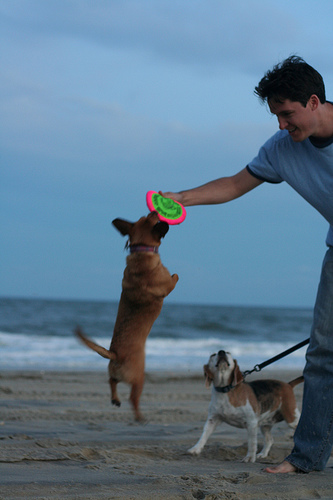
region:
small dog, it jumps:
[68, 202, 187, 427]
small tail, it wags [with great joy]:
[66, 317, 119, 366]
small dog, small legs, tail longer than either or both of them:
[68, 322, 154, 429]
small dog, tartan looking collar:
[118, 239, 159, 258]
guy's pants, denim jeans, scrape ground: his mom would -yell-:
[281, 242, 332, 474]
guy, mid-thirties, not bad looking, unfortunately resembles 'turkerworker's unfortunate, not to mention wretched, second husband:
[252, 45, 331, 157]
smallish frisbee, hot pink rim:
[143, 187, 190, 227]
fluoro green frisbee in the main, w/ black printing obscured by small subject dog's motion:
[149, 192, 182, 218]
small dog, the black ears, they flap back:
[108, 216, 176, 246]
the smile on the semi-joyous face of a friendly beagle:
[213, 345, 231, 371]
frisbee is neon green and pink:
[120, 180, 201, 245]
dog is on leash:
[200, 311, 309, 420]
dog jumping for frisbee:
[113, 182, 199, 417]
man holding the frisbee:
[145, 143, 248, 235]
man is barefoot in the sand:
[251, 443, 331, 493]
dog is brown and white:
[200, 332, 303, 487]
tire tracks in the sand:
[18, 367, 100, 449]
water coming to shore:
[31, 325, 75, 385]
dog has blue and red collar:
[109, 237, 177, 261]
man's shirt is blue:
[243, 131, 331, 185]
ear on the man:
[307, 96, 321, 110]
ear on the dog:
[198, 362, 213, 386]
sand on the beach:
[51, 427, 126, 472]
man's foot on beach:
[265, 461, 294, 477]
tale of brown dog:
[69, 328, 112, 361]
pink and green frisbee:
[148, 189, 184, 222]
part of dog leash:
[241, 349, 301, 373]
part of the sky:
[23, 97, 157, 149]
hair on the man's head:
[292, 68, 316, 93]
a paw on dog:
[238, 450, 257, 464]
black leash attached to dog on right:
[253, 342, 320, 372]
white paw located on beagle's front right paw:
[190, 431, 218, 460]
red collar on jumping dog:
[113, 228, 171, 276]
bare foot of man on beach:
[257, 456, 309, 479]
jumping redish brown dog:
[68, 208, 177, 436]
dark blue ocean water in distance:
[11, 289, 97, 331]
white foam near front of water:
[23, 329, 61, 368]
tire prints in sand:
[26, 385, 106, 455]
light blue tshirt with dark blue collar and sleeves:
[237, 127, 331, 225]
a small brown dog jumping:
[80, 205, 177, 415]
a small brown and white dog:
[185, 342, 303, 461]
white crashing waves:
[1, 329, 326, 368]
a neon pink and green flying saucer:
[142, 186, 189, 227]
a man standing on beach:
[158, 56, 331, 476]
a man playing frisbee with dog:
[72, 59, 330, 478]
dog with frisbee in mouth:
[67, 187, 188, 419]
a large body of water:
[2, 293, 315, 376]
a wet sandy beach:
[0, 371, 330, 492]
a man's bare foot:
[259, 456, 298, 476]